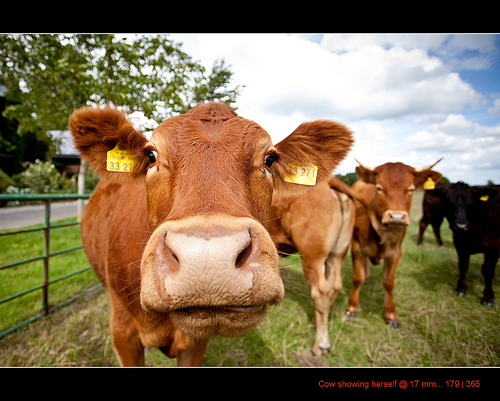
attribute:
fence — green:
[1, 190, 103, 340]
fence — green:
[19, 196, 89, 333]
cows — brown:
[68, 104, 498, 366]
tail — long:
[329, 173, 376, 219]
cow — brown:
[52, 96, 351, 396]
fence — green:
[0, 181, 119, 360]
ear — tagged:
[67, 105, 148, 177]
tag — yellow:
[97, 142, 167, 186]